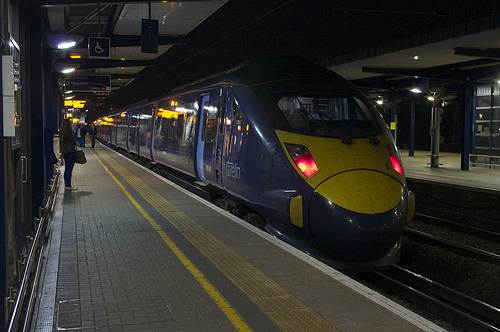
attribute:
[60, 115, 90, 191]
woman — standing, waiting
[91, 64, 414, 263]
train — yellow, blue, subway train, large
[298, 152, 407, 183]
headlights — red, on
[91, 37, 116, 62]
handicapped sign — showing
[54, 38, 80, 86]
lights — on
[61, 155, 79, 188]
jeans — blue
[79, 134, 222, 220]
sidewalk — grey concrete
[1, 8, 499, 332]
scene — nighttime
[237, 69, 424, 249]
train front — yellow, blue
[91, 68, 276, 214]
whole train — blue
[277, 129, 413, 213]
front — yellow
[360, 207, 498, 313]
track — below